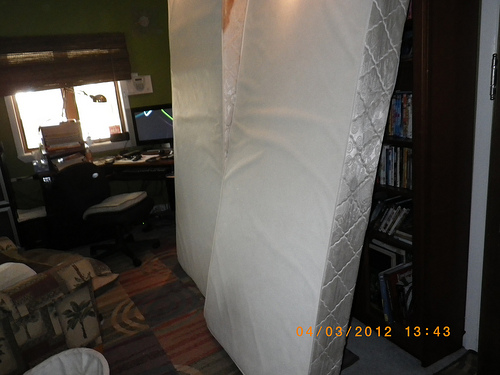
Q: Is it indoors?
A: Yes, it is indoors.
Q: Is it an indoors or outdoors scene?
A: It is indoors.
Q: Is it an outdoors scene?
A: No, it is indoors.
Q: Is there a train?
A: No, there are no trains.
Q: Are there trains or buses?
A: No, there are no trains or buses.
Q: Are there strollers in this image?
A: No, there are no strollers.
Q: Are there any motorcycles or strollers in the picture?
A: No, there are no strollers or motorcycles.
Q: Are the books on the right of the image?
A: Yes, the books are on the right of the image.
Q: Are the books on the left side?
A: No, the books are on the right of the image.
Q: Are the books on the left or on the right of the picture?
A: The books are on the right of the image.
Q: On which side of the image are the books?
A: The books are on the right of the image.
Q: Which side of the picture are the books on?
A: The books are on the right of the image.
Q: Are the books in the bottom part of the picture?
A: Yes, the books are in the bottom of the image.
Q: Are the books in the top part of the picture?
A: No, the books are in the bottom of the image.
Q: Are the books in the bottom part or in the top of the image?
A: The books are in the bottom of the image.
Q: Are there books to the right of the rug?
A: Yes, there are books to the right of the rug.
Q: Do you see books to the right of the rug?
A: Yes, there are books to the right of the rug.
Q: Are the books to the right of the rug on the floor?
A: Yes, the books are to the right of the rug.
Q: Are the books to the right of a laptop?
A: No, the books are to the right of the rug.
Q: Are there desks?
A: Yes, there is a desk.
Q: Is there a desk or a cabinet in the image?
A: Yes, there is a desk.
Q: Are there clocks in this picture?
A: No, there are no clocks.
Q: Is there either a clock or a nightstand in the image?
A: No, there are no clocks or nightstands.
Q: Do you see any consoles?
A: No, there are no consoles.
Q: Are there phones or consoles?
A: No, there are no consoles or phones.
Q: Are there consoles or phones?
A: No, there are no consoles or phones.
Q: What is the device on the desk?
A: The device is a computer monitor.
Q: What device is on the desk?
A: The device is a computer monitor.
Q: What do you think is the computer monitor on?
A: The computer monitor is on the desk.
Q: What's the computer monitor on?
A: The computer monitor is on the desk.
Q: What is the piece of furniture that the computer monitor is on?
A: The piece of furniture is a desk.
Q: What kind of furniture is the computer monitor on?
A: The computer monitor is on the desk.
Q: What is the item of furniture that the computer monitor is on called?
A: The piece of furniture is a desk.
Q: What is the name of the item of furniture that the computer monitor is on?
A: The piece of furniture is a desk.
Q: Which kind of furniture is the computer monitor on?
A: The computer monitor is on the desk.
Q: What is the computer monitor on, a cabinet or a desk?
A: The computer monitor is on a desk.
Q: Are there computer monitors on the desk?
A: Yes, there is a computer monitor on the desk.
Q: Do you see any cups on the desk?
A: No, there is a computer monitor on the desk.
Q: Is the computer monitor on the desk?
A: Yes, the computer monitor is on the desk.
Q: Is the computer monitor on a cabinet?
A: No, the computer monitor is on the desk.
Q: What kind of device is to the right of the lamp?
A: The device is a computer monitor.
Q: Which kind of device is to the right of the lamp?
A: The device is a computer monitor.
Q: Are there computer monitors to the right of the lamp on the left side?
A: Yes, there is a computer monitor to the right of the lamp.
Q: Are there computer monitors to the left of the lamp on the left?
A: No, the computer monitor is to the right of the lamp.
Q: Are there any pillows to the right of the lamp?
A: No, there is a computer monitor to the right of the lamp.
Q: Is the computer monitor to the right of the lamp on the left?
A: Yes, the computer monitor is to the right of the lamp.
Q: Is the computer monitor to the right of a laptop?
A: No, the computer monitor is to the right of the lamp.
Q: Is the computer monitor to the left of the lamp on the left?
A: No, the computer monitor is to the right of the lamp.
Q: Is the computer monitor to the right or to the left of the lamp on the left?
A: The computer monitor is to the right of the lamp.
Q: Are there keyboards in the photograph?
A: Yes, there is a keyboard.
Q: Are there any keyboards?
A: Yes, there is a keyboard.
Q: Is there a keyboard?
A: Yes, there is a keyboard.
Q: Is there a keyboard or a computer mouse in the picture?
A: Yes, there is a keyboard.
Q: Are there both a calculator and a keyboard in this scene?
A: No, there is a keyboard but no calculators.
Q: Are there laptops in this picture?
A: No, there are no laptops.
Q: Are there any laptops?
A: No, there are no laptops.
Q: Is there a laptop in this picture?
A: No, there are no laptops.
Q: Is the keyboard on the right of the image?
A: No, the keyboard is on the left of the image.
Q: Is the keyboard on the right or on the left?
A: The keyboard is on the left of the image.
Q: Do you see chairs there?
A: Yes, there is a chair.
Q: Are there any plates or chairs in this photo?
A: Yes, there is a chair.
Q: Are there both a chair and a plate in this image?
A: No, there is a chair but no plates.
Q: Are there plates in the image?
A: No, there are no plates.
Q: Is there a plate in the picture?
A: No, there are no plates.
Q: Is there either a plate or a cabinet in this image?
A: No, there are no plates or cabinets.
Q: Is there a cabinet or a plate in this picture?
A: No, there are no plates or cabinets.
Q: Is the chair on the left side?
A: Yes, the chair is on the left of the image.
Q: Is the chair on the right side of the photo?
A: No, the chair is on the left of the image.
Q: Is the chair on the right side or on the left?
A: The chair is on the left of the image.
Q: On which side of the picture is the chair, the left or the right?
A: The chair is on the left of the image.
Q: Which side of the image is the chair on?
A: The chair is on the left of the image.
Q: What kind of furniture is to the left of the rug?
A: The piece of furniture is a chair.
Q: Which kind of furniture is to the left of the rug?
A: The piece of furniture is a chair.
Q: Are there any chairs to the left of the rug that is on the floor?
A: Yes, there is a chair to the left of the rug.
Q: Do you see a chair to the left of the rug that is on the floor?
A: Yes, there is a chair to the left of the rug.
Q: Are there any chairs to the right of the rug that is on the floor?
A: No, the chair is to the left of the rug.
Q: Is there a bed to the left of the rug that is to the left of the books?
A: No, there is a chair to the left of the rug.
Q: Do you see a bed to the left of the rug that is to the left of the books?
A: No, there is a chair to the left of the rug.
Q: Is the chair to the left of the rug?
A: Yes, the chair is to the left of the rug.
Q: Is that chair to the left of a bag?
A: No, the chair is to the left of the rug.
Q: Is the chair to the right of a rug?
A: No, the chair is to the left of a rug.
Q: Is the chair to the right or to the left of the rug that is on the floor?
A: The chair is to the left of the rug.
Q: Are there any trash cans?
A: No, there are no trash cans.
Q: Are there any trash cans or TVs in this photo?
A: No, there are no trash cans or tvs.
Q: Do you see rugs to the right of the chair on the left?
A: Yes, there is a rug to the right of the chair.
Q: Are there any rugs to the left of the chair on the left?
A: No, the rug is to the right of the chair.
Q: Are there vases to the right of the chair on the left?
A: No, there is a rug to the right of the chair.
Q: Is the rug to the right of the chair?
A: Yes, the rug is to the right of the chair.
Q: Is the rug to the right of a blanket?
A: No, the rug is to the right of the chair.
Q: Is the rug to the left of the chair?
A: No, the rug is to the right of the chair.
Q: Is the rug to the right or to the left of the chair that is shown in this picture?
A: The rug is to the right of the chair.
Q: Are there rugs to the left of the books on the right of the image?
A: Yes, there is a rug to the left of the books.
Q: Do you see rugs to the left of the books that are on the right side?
A: Yes, there is a rug to the left of the books.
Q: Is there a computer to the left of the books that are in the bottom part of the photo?
A: No, there is a rug to the left of the books.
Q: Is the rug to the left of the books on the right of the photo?
A: Yes, the rug is to the left of the books.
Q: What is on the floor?
A: The rug is on the floor.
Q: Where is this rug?
A: The rug is on the floor.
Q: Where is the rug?
A: The rug is on the floor.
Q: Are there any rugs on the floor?
A: Yes, there is a rug on the floor.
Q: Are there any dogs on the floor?
A: No, there is a rug on the floor.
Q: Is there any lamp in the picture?
A: Yes, there is a lamp.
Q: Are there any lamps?
A: Yes, there is a lamp.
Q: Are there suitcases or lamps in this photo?
A: Yes, there is a lamp.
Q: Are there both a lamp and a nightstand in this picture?
A: No, there is a lamp but no nightstands.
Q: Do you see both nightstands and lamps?
A: No, there is a lamp but no nightstands.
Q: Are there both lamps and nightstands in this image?
A: No, there is a lamp but no nightstands.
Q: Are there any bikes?
A: No, there are no bikes.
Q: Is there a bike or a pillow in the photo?
A: No, there are no bikes or pillows.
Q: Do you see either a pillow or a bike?
A: No, there are no bikes or pillows.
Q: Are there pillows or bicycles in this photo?
A: No, there are no bicycles or pillows.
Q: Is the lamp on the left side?
A: Yes, the lamp is on the left of the image.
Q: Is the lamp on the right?
A: No, the lamp is on the left of the image.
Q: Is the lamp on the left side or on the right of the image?
A: The lamp is on the left of the image.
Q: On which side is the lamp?
A: The lamp is on the left of the image.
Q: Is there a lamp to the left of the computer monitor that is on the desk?
A: Yes, there is a lamp to the left of the computer monitor.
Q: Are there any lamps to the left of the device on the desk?
A: Yes, there is a lamp to the left of the computer monitor.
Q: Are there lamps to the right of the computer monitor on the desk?
A: No, the lamp is to the left of the computer monitor.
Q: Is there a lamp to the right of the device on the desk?
A: No, the lamp is to the left of the computer monitor.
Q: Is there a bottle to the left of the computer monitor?
A: No, there is a lamp to the left of the computer monitor.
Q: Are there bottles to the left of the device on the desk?
A: No, there is a lamp to the left of the computer monitor.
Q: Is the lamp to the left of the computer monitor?
A: Yes, the lamp is to the left of the computer monitor.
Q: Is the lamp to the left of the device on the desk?
A: Yes, the lamp is to the left of the computer monitor.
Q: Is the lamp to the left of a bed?
A: No, the lamp is to the left of the computer monitor.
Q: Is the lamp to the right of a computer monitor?
A: No, the lamp is to the left of a computer monitor.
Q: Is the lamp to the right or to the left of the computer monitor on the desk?
A: The lamp is to the left of the computer monitor.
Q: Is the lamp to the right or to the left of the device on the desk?
A: The lamp is to the left of the computer monitor.